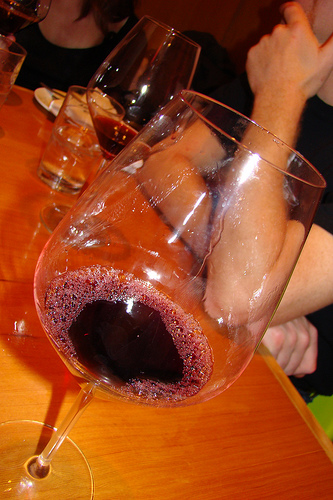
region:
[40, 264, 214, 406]
Purple colored wine in a glass with lots of little bubbles.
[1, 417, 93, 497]
Clear glass round base of a wine glass on the bottom left.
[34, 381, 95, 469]
Tall thin stem of a close wine glass.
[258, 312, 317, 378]
Right hand of a person sitting closest to the camera.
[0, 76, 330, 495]
Brown table people are sitting at.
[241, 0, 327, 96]
Left hand of a man.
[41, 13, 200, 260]
Second wineglass on the brown table.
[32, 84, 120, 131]
White plate in front of woman wearing black.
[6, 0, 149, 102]
Woman wearing a black top.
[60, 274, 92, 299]
Lots of little bubbles in purple colored wine.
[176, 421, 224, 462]
a section of table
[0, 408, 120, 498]
the base of a wine glass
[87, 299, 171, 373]
red wine in a glass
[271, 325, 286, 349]
the left red knuckle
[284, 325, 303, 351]
the second red knuckle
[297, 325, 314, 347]
the third red knuckle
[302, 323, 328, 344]
the right red knuckle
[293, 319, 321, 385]
the red pointer finger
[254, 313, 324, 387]
a red fisted hand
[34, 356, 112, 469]
the wine glass stem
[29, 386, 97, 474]
the stem of a wine glass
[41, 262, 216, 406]
red wine in the glass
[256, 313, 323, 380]
the hand of a person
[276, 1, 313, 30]
the finger of a person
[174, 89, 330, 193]
the mouth of a wine glass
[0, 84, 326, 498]
a large wine glass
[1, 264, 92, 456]
a shadow on the table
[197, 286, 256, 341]
the elbow of the person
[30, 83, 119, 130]
a white plate on the table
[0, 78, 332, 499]
a brown wooden table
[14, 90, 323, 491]
a glass of red wine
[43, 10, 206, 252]
a glass of red wine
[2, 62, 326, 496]
a wooden table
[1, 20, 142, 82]
a black woman's shirt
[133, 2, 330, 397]
a man in a black tshirt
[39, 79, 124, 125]
a metal knife on a white ceramic plate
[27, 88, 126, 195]
a small glass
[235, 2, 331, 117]
a hand touching a face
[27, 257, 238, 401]
bubbles in red wine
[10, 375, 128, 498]
the stem of a wine glass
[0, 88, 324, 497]
a glass with wine in it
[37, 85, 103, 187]
a short drinking glass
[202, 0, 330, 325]
a man's left elbow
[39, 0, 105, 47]
a woman's cleavage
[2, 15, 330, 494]
three glasses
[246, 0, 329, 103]
a man's left hand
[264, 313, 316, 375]
a man's right hand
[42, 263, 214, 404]
wine in bottom of glass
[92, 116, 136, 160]
some wine in glass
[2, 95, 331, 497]
a long wooden table